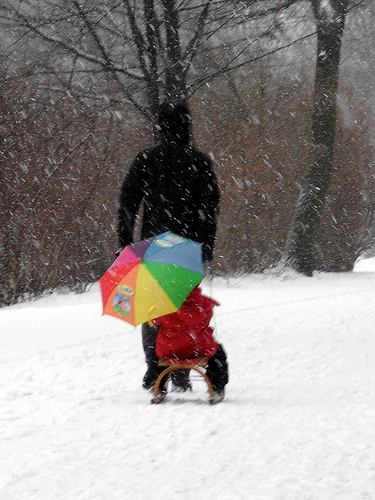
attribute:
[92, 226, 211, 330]
umbrella — colorful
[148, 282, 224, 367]
jacket — red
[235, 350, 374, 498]
snow — white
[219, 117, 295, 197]
weather — snow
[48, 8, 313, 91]
tree — woody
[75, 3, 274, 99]
tree — dry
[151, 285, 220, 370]
jacket — red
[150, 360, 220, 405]
sled — wooden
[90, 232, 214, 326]
umbrella — rainbow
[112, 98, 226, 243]
adult — black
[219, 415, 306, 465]
snow — white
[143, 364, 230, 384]
pants — black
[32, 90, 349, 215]
snowfall — heavy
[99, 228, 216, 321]
umbrella — rainbow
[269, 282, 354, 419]
snow — white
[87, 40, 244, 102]
trees — leafless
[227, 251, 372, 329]
area — hilly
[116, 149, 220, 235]
jacket — black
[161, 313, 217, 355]
jacket — red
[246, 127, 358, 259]
vegetation — brown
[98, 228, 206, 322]
umbrella — rainbow, colorful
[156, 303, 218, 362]
jacket — red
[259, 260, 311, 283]
pile — snow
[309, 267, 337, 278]
pile — snow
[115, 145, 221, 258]
jacket — black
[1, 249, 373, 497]
snow — pure, white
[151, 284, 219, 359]
jacket — red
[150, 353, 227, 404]
seigh — rounded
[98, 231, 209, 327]
umbrella — rainbow, colored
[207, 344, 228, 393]
pants — black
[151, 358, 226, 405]
sleigh — brown, rounded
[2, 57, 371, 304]
bushes — row of, bare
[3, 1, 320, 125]
tree — large, bare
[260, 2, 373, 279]
tree — large, bare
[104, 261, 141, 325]
section — orange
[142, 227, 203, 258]
section — blue